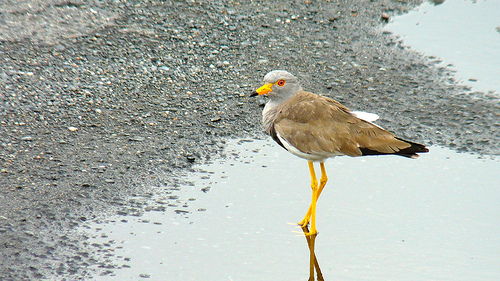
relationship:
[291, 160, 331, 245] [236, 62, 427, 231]
wading small bird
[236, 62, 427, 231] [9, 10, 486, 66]
bird on beach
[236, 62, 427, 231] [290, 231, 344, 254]
bird in water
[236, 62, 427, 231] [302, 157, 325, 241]
bird has long legs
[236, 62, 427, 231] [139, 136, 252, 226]
bird on ground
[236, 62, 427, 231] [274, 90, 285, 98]
bird head gray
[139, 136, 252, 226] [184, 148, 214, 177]
ground has stones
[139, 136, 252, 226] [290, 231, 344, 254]
ground has water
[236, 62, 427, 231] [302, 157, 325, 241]
bird has yellow legs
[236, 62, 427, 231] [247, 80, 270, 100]
bird has a beak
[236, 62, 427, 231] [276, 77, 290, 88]
bird has eye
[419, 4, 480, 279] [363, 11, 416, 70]
shore with gravel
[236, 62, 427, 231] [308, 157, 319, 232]
bird has legs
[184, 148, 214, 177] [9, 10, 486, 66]
stones on beach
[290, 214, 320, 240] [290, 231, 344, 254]
foot in water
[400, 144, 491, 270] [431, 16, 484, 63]
puddle next to puddle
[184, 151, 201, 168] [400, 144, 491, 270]
rock near puddle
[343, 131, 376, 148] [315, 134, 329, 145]
brown feather under tan feathers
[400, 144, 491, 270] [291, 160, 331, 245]
puddle of wading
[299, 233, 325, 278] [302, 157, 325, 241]
reflection of legs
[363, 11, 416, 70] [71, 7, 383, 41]
gravel on road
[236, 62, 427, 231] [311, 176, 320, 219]
bird legs yellow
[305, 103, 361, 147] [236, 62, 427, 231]
feathers on a bird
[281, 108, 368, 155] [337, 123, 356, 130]
wing feathers brown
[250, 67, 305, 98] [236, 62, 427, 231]
head on a bird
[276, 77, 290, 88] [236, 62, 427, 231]
eye on a bird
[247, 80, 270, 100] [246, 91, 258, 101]
beak with black tip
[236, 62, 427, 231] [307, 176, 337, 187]
bird of bent leg